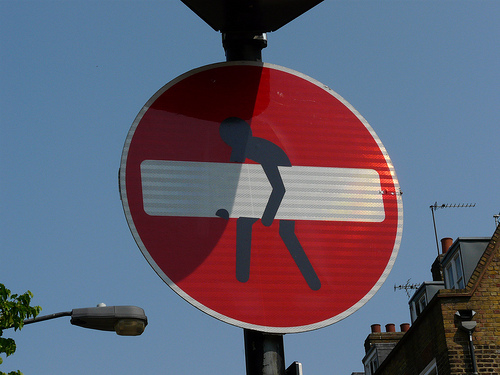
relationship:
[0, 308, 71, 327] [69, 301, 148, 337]
pole holding light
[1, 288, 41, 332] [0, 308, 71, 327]
leaves front of pole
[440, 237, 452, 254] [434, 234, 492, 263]
chimney on roof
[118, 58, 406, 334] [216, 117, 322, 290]
sign with human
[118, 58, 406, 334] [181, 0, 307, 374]
sign on pole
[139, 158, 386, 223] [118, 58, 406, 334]
rectangle on sign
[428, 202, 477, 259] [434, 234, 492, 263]
antenna on roof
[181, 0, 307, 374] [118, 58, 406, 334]
pole holding sign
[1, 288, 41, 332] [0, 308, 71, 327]
leaves by pole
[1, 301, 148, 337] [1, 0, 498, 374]
light against sky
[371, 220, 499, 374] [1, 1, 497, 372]
building in background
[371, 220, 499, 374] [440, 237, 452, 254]
building has chimney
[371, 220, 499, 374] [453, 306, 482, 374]
building has pipe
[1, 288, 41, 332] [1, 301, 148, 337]
leaves near light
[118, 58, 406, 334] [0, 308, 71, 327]
sign on pole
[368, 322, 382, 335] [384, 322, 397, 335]
chimney next to chimney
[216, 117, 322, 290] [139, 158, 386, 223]
human carrying rectangle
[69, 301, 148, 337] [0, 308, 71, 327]
light on pole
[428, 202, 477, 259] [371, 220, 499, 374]
antenna on building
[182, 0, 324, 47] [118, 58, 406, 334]
light on top of sign